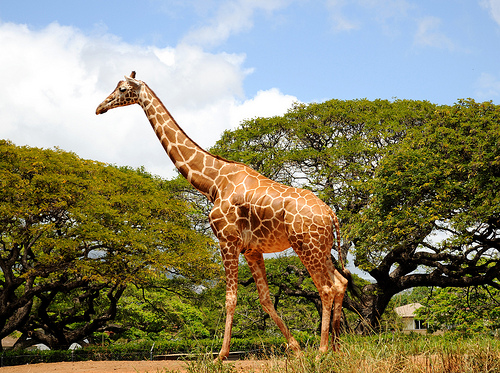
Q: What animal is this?
A: Giraffe.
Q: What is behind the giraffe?
A: Trees.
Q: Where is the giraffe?
A: Field.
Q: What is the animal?
A: Giraffe.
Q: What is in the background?
A: Tree.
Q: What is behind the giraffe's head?
A: Clouds.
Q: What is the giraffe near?
A: Trees.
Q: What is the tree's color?
A: Green.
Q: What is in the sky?
A: Clouds.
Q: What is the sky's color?
A: Blue.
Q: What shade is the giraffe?
A: Brown.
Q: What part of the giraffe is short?
A: Mane.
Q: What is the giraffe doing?
A: Standing.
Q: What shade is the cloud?
A: White.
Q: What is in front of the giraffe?
A: Grass.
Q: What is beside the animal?
A: Trees.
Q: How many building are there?
A: Two.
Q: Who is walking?
A: A giraffe.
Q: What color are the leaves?
A: Green.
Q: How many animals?
A: One.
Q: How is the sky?
A: Sunny.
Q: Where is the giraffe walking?
A: The dirt.